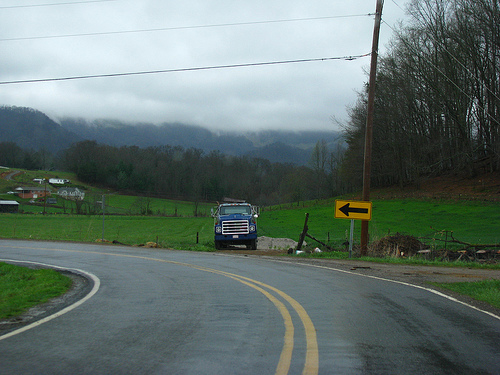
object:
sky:
[0, 0, 499, 143]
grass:
[0, 165, 499, 269]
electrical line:
[0, 51, 372, 84]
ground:
[0, 198, 499, 373]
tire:
[246, 239, 256, 252]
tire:
[212, 239, 227, 251]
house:
[53, 186, 85, 202]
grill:
[220, 218, 251, 236]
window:
[222, 205, 247, 215]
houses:
[0, 198, 23, 215]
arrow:
[336, 203, 371, 218]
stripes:
[0, 243, 319, 373]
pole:
[345, 219, 355, 256]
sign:
[332, 199, 373, 222]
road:
[0, 238, 499, 375]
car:
[211, 197, 260, 252]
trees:
[328, 0, 499, 200]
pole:
[358, 0, 388, 257]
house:
[48, 178, 71, 187]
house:
[6, 186, 51, 202]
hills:
[0, 165, 217, 216]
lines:
[196, 266, 296, 372]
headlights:
[248, 223, 257, 235]